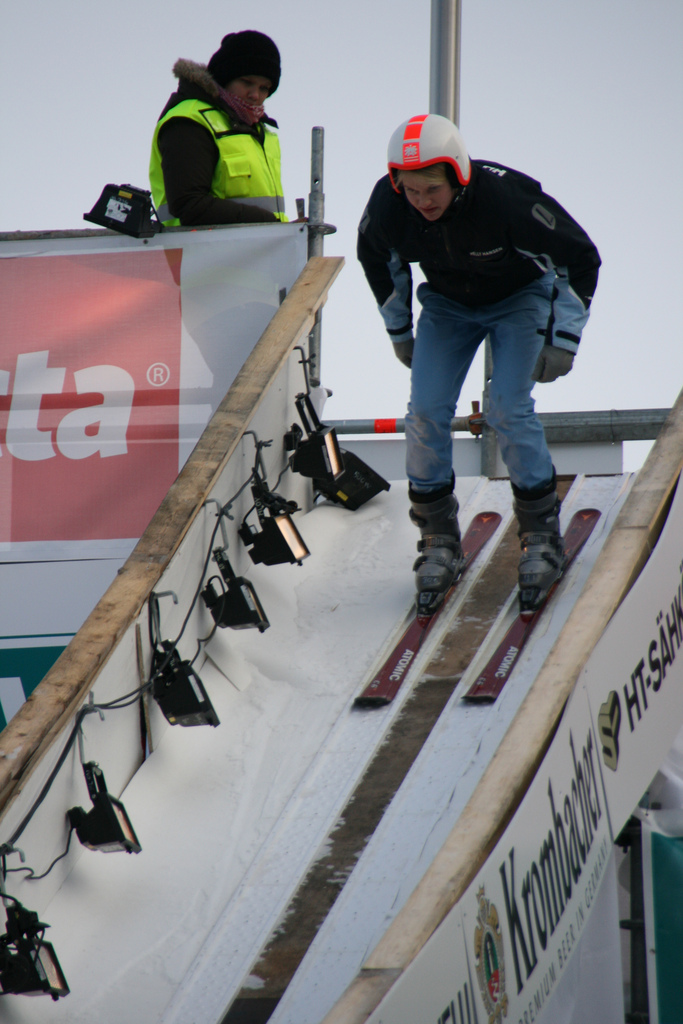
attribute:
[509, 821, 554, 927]
letters — BLACK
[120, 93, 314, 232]
vest — neon, green